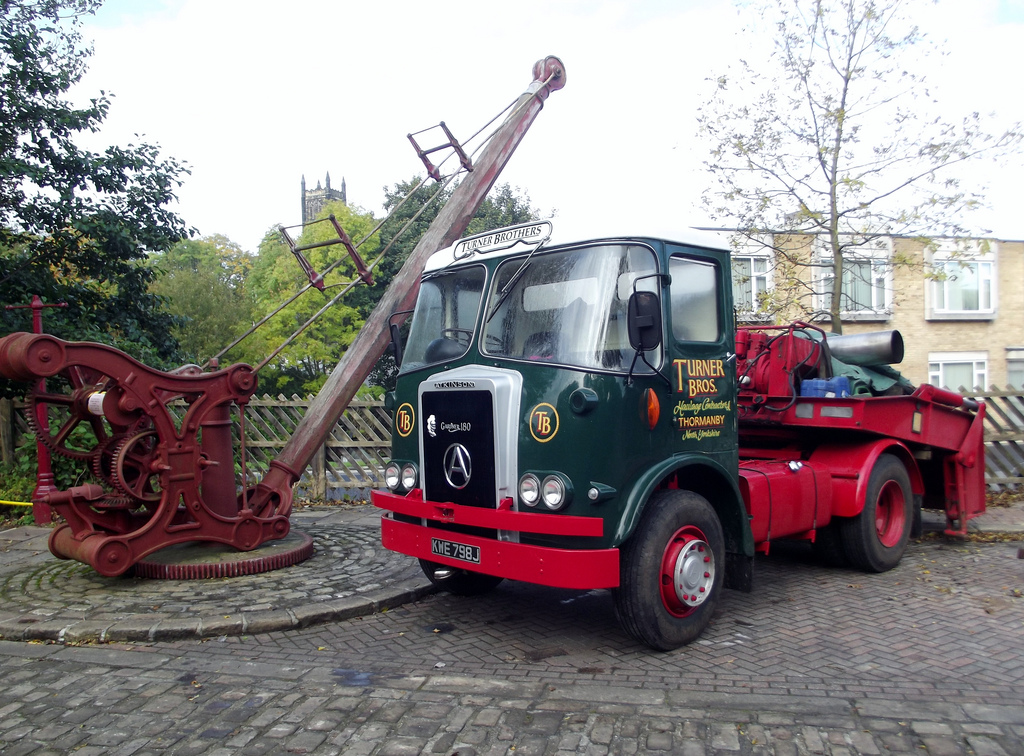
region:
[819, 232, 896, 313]
window on top of building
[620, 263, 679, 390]
side mirror attached to truck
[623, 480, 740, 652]
truck is attached to truck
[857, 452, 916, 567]
tire is attached to truck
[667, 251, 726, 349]
window attached to truck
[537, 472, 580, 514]
light attached to truck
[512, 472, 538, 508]
light attached to truck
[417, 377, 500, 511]
grill on front of truck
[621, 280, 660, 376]
mirror on side of truck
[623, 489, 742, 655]
front tire on truck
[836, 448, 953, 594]
back tire on truck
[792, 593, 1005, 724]
brick pavement on ground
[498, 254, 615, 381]
left windshield on truck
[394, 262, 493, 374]
right windshield on truck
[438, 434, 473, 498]
logo on front of truck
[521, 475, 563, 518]
pair of headlights on front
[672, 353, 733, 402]
yellow print on door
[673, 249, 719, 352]
side window on truck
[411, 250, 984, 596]
the truck is green and red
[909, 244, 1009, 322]
the window is closed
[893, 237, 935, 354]
the building is brown in color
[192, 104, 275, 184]
the sky is blue in color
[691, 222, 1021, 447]
Beige building with white windows.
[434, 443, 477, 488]
The letter A in a circle on the vehicle.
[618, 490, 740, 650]
Front wheel with silver center.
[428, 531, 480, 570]
Black license plate with silver letters and numbers.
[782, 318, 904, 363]
Large metal pipe on back of vehicle.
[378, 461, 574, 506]
Four white headlights on front of vehicle.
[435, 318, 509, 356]
Black steering wheel inside of vehicle.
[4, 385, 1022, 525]
Long brown wooden fence.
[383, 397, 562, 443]
Two yellow circles with the letters TB.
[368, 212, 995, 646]
Green and red vehicle with black tires.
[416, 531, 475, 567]
license plate on the bumper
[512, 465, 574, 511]
headlight on the truck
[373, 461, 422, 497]
headlight on the truck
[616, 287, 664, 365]
mirror on the truck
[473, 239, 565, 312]
windshield wiper on the truck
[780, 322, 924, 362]
metal pole on the truck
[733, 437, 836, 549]
red gas tank on the truck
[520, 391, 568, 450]
yellow logo on front of truck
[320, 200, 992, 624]
red green and black towing truck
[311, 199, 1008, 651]
red green and black towing truck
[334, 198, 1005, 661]
red green and black towing truck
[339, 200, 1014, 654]
red green and black towing truck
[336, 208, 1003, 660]
red green and black towing truck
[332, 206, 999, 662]
red green and black towing truck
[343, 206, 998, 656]
red green and black towing truck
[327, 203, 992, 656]
red green and black towing truck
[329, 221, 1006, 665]
red green and black towing truck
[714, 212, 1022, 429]
a light brick building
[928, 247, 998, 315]
a window on the building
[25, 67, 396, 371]
tall trees next to the building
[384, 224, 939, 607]
a large red and green truck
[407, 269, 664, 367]
the windshield on the truck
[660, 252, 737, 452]
the door on the truck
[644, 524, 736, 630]
a tire on the truck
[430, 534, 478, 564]
the license plate on the truck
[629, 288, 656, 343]
the side mirror on the truck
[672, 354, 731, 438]
writing on the truck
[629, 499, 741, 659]
front wheel